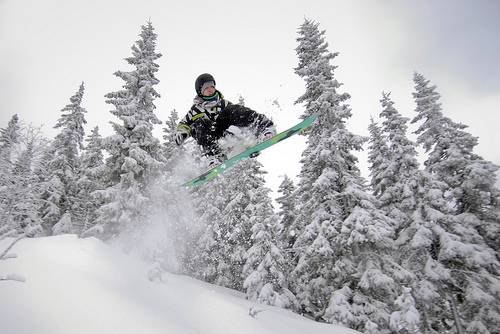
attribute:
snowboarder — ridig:
[172, 58, 321, 192]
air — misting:
[1, 2, 498, 250]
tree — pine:
[88, 22, 168, 250]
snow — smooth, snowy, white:
[3, 236, 387, 328]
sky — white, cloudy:
[1, 1, 498, 197]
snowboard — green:
[181, 109, 319, 192]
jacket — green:
[178, 99, 235, 130]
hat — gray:
[202, 82, 217, 94]